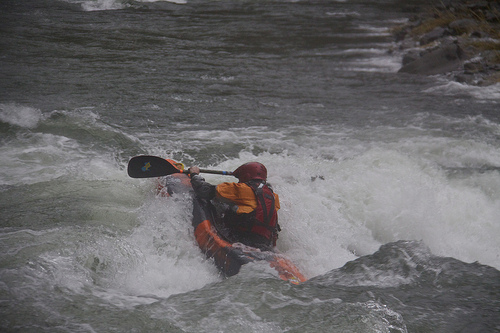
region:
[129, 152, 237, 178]
paddle in the hands of a person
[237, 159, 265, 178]
red helmet on the person's head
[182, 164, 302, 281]
canoe in the rapids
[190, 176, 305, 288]
blue and gold canoe in the rapids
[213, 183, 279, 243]
yellow shirt and red vest on boater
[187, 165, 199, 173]
left hand gripping the paddle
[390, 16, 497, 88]
rocks on the shoreline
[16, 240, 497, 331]
water on top of a large rock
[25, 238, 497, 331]
large rock in the water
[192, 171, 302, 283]
canoe tipping at an angle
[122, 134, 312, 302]
man in orange canoe in rapid waters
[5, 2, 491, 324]
gray waters with rapid moving waves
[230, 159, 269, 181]
man wearing red helmet in orange canoe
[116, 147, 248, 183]
man holding black and orange paddle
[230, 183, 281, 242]
man wearing red life vest in canoe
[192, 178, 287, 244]
man in orange jacket under red life vest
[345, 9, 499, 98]
rocky formations with green grassy mounds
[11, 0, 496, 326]
outdoor overcast daytime canoing scene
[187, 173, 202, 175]
man wearing black wrist watch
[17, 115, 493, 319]
large white foaming wave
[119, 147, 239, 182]
an oar in a hand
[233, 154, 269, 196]
a hat on a kayaker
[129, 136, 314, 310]
kayaker in the water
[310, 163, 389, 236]
white crashing waves in the river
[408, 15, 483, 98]
big rocks along the shoreline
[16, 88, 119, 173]
white foam on top of the water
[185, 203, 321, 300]
orange and black kayak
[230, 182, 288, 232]
red and black life vest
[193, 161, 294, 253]
a kayaker in a life vest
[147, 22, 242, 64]
calm part of a river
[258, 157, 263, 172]
part of a jacket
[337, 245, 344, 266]
edge of a wave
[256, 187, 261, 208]
part of a jacket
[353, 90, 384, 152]
part of a rock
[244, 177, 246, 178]
part of an helmet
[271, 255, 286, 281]
side of a boat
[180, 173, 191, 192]
edge of a row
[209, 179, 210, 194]
part of a paddle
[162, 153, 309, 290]
the kayak is orange and black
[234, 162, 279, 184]
the helmet is red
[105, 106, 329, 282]
the person is kayaking in the water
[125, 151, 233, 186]
the paddle is black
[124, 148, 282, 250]
the person is holding the paddle in their hand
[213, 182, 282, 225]
the jacket is orange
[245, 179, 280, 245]
the lifevest is red and black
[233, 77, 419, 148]
the water is dark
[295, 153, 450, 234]
the waves are white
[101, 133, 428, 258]
the person is paddling in the waves